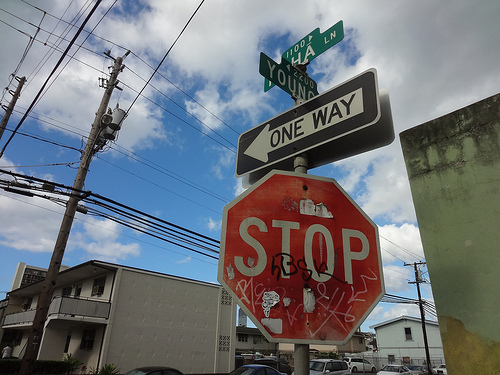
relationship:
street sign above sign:
[258, 51, 320, 103] [232, 65, 396, 193]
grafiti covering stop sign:
[230, 258, 361, 330] [218, 165, 387, 345]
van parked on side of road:
[303, 350, 360, 374] [306, 353, 468, 373]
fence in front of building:
[398, 357, 442, 367] [375, 310, 434, 372]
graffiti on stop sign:
[231, 250, 380, 334] [218, 165, 387, 345]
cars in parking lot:
[241, 355, 445, 372] [238, 352, 445, 372]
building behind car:
[2, 257, 240, 374] [374, 361, 412, 374]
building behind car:
[2, 257, 240, 374] [346, 353, 377, 370]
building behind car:
[2, 257, 240, 374] [433, 362, 448, 372]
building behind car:
[2, 257, 240, 374] [231, 361, 283, 370]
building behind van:
[2, 257, 240, 374] [290, 358, 353, 374]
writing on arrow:
[266, 93, 353, 148] [238, 86, 364, 162]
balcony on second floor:
[49, 297, 108, 322] [4, 265, 218, 327]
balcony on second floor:
[4, 310, 40, 327] [4, 265, 218, 327]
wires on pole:
[78, 190, 220, 260] [18, 53, 124, 374]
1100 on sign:
[282, 35, 305, 58] [264, 20, 344, 91]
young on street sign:
[266, 54, 313, 104] [258, 53, 316, 101]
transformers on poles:
[87, 94, 137, 159] [20, 150, 96, 366]